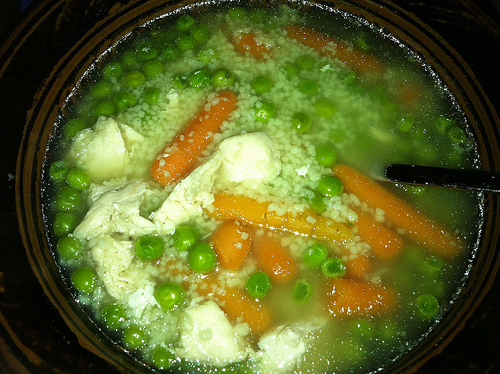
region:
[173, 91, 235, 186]
carrots in the pan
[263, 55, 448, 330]
peas and carrots in the pot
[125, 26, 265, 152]
pasta and peas together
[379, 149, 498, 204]
spoon is black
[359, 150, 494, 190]
spoon is in the pot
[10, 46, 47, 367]
dish under soup is gold and black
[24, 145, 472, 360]
a bowl of soup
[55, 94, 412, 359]
vegetables in the soup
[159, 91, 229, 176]
carrot is orange in color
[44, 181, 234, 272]
peas are green and big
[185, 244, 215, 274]
green pea in mixture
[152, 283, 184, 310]
green pea in mixture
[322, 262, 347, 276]
green pea in mixture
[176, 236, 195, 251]
green pea in mixture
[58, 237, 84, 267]
green pea in mixture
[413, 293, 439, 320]
green pea in mixture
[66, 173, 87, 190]
green pea in mixture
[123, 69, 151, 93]
green pea in mixture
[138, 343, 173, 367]
green pea in mixture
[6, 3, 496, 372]
soup in black and gold bowl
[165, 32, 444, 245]
whole carrots in soup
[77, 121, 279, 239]
chunks of white meat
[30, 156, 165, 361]
green peas around edge of bowl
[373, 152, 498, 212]
spoon handle over soup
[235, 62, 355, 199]
small pices of pasta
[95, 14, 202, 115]
green peas under water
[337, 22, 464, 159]
vegetables in chicken broth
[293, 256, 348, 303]
dented peas in soup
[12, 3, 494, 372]
gold rings around bowl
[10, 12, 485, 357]
soup in a bowl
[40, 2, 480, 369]
carrots are in the soup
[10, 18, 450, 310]
baby carrots in a soup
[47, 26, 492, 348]
peas in a soup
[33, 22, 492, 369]
carrots in a bowl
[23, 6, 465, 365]
baby carrots in a bowl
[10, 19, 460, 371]
peas in a bowl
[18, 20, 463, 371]
a bowl with carrots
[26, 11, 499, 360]
a bowl with peas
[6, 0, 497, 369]
bowl of soup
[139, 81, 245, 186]
small carrot in bowl of soup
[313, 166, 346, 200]
pea in bow of soup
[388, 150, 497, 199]
utensil leaning on edge of bowl of soup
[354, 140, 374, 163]
clear yellow soup broth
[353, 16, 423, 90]
reflection of light on edge of bowl of soup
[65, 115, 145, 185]
white chunks in bowl of white soup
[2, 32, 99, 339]
tan stripes on edge of bowl of soup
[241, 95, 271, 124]
small white seasoning in broth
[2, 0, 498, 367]
large , round, dark brown bowl